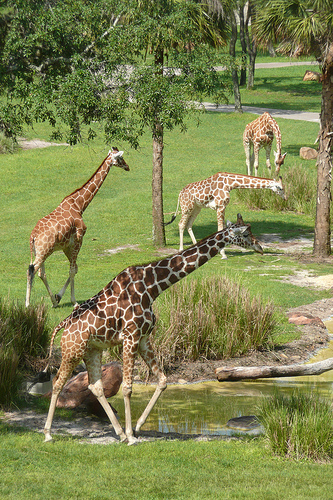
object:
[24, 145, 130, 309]
giraffe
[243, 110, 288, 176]
giraffe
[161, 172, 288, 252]
giraffe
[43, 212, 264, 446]
giraffe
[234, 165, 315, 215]
grass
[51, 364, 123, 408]
boulder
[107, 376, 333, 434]
water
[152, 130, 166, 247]
trunk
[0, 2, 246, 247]
tree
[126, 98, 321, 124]
pathway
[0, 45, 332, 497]
grounds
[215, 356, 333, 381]
log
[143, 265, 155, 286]
spot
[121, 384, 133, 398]
knee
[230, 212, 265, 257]
head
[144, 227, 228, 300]
neck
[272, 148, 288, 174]
head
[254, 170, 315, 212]
food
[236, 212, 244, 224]
horns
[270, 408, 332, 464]
grass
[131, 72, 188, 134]
leaves